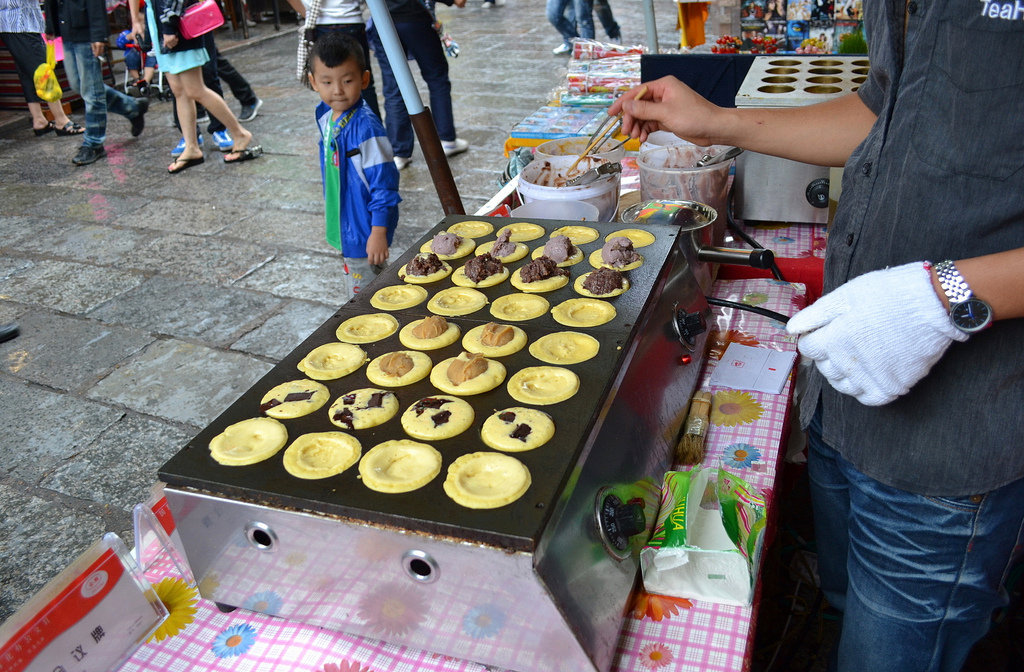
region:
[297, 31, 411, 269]
a boy wearing a green shirt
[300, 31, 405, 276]
a boy wearing a blue jacket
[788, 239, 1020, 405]
a person's hand wearing gloves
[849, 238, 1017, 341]
a person's hand wearing a wrist watch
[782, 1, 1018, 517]
a person wearing a grey shirt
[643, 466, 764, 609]
a pack of tissue papers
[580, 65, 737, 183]
a hand holding a pair of chopsticks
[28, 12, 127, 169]
a man holding a bag and a cigarette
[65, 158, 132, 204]
a stone in the floor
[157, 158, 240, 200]
a stone in the floor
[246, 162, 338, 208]
a stone in the floor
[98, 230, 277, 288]
a stone in the floor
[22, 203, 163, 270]
a stone in the floor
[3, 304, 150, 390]
a stone in the floor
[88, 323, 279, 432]
a stone in the floor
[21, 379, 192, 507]
a stone in the floor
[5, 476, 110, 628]
a stone in the floor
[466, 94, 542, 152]
a stone in the floor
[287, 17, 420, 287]
the kid has blue jacket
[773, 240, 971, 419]
the glove is white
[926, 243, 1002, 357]
the watch is color silver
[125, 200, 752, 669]
the stove is silver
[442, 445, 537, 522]
the bread on the burner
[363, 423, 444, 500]
the bread on the burner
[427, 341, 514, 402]
chocolate cream on a bread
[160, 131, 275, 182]
the sandals are black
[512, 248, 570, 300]
chocolate cream on a bread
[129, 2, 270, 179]
person has a blue dress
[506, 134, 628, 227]
a pail with chocolate cream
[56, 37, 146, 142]
a pair of blue jeans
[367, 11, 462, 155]
a pair of blue jeans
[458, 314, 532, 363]
chocolate cream on a bread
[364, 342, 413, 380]
chocolate cream on a bread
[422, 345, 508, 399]
chocolate cream on a bread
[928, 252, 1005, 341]
clock on a wrist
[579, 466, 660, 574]
a knob on a stove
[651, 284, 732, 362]
a knob on a stove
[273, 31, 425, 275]
small child is watching the person cook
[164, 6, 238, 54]
person has a pink purse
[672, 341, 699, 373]
red light is on the grill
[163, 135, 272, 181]
person is wearing flip flops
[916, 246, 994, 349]
person is wearing a watch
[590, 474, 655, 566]
black knob on the grill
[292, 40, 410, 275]
boy is wearing a blue and grey jacket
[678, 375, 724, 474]
pastry brush laying by the grill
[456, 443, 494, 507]
food on the griddle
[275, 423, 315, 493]
food on the griddle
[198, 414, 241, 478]
food on the griddle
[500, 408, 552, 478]
food on the griddle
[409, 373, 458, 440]
food on the griddle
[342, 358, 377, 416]
food on the griddle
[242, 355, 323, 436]
food on the griddle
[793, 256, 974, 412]
The glove on the man's hand.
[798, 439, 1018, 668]
The jeans the man behind the table is wearing.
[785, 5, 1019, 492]
The gray shirt the man behind the table is wearing.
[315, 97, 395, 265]
The jacket the boy is wearing.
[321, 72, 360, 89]
The eyes of the young boy in the blue jacket.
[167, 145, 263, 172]
The sandals the lady in the light blue skirt is wearing.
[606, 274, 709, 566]
The knobs on the cooking stove.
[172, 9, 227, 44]
The pink purse the woman is holding.